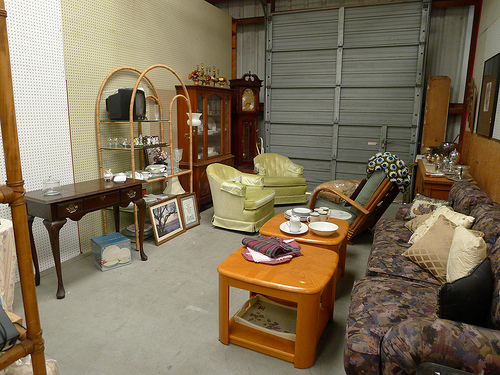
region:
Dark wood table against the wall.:
[32, 172, 152, 299]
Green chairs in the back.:
[206, 140, 307, 230]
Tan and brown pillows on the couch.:
[400, 205, 485, 287]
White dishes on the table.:
[282, 205, 343, 237]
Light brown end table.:
[211, 235, 336, 363]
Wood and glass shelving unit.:
[100, 64, 201, 230]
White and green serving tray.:
[234, 297, 305, 343]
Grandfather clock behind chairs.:
[230, 69, 264, 171]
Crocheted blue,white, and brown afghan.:
[364, 150, 411, 187]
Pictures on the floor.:
[149, 192, 204, 241]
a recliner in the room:
[300, 145, 413, 225]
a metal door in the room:
[260, 4, 437, 204]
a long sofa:
[345, 186, 499, 372]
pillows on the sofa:
[407, 187, 488, 322]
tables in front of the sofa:
[214, 202, 346, 373]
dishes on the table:
[277, 202, 352, 243]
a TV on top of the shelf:
[104, 84, 156, 120]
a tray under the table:
[235, 290, 300, 342]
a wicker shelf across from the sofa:
[92, 57, 194, 242]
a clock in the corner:
[227, 64, 266, 175]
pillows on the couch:
[415, 189, 467, 284]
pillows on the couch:
[389, 198, 484, 343]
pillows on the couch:
[402, 189, 457, 255]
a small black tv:
[105, 85, 138, 115]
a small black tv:
[91, 72, 188, 137]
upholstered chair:
[204, 158, 279, 238]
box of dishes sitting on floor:
[87, 229, 135, 273]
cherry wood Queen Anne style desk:
[18, 172, 148, 298]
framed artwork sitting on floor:
[147, 193, 188, 248]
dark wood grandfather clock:
[228, 68, 265, 173]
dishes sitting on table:
[278, 203, 340, 237]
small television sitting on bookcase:
[101, 86, 153, 123]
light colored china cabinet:
[174, 84, 234, 221]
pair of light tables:
[216, 201, 353, 371]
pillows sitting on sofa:
[400, 213, 487, 290]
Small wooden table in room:
[209, 235, 349, 352]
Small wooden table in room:
[284, 202, 359, 256]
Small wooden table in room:
[34, 151, 151, 266]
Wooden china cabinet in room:
[183, 88, 234, 198]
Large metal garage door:
[243, 32, 403, 195]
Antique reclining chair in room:
[305, 160, 406, 238]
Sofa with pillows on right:
[345, 148, 499, 370]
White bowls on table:
[273, 199, 375, 255]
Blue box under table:
[84, 227, 141, 274]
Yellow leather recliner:
[208, 163, 275, 234]